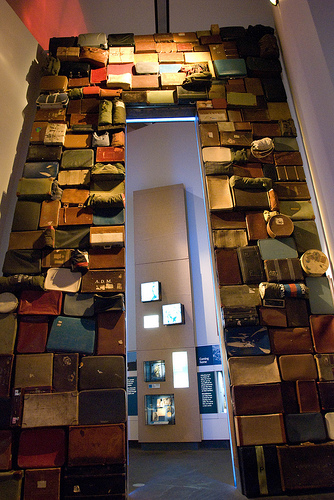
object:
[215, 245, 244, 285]
wallets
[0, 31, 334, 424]
display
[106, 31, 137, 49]
wallets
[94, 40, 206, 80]
light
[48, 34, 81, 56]
wallet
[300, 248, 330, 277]
box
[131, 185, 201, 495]
frames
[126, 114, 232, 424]
mirror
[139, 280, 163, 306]
wallet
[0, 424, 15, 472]
pouches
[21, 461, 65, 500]
pouches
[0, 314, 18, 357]
pouches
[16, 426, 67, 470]
pouches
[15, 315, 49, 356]
pouches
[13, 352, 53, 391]
pouches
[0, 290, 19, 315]
pouches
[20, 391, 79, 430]
pouches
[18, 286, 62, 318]
pouches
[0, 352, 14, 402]
pouches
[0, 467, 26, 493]
writing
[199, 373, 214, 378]
writing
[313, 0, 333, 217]
wall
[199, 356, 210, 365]
writing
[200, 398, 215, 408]
writing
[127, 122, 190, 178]
wall